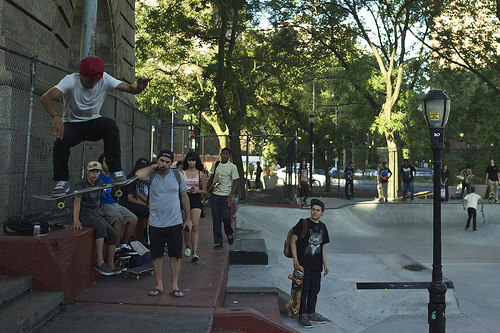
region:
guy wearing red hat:
[73, 53, 109, 85]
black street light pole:
[411, 81, 461, 331]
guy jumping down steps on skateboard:
[16, 50, 161, 217]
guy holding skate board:
[276, 190, 337, 328]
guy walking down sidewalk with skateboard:
[204, 139, 245, 256]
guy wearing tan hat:
[82, 155, 109, 176]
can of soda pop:
[30, 219, 42, 239]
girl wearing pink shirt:
[174, 153, 211, 199]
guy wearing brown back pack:
[279, 191, 332, 331]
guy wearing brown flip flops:
[143, 281, 187, 302]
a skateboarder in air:
[31, 56, 154, 206]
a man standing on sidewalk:
[132, 150, 192, 301]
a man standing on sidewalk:
[283, 198, 331, 330]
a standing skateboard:
[285, 260, 304, 318]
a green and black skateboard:
[31, 170, 142, 210]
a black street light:
[416, 81, 453, 331]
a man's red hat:
[75, 54, 103, 74]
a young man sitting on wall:
[75, 159, 120, 280]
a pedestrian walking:
[205, 145, 239, 250]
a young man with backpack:
[281, 199, 331, 327]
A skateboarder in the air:
[27, 55, 154, 210]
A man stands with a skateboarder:
[285, 192, 327, 332]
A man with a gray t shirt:
[140, 150, 193, 305]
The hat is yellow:
[84, 158, 104, 172]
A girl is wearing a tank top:
[183, 149, 205, 204]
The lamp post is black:
[419, 90, 466, 331]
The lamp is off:
[417, 85, 452, 151]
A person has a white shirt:
[463, 183, 488, 231]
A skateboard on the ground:
[128, 265, 156, 280]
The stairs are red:
[226, 285, 315, 331]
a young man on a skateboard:
[35, 50, 151, 222]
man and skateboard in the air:
[26, 55, 153, 244]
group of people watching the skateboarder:
[32, 47, 262, 293]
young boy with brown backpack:
[282, 191, 339, 329]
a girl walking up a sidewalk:
[176, 147, 233, 281]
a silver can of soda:
[29, 217, 44, 243]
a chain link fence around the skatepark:
[2, 31, 497, 259]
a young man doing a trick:
[26, 52, 164, 210]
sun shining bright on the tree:
[357, 30, 412, 200]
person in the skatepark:
[276, 201, 340, 321]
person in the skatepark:
[146, 145, 193, 303]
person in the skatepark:
[45, 65, 120, 189]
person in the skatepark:
[446, 185, 487, 241]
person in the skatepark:
[205, 140, 238, 243]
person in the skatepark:
[80, 161, 118, 254]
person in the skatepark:
[170, 146, 206, 221]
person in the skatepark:
[362, 157, 402, 207]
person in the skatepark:
[293, 153, 313, 199]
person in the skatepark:
[334, 160, 359, 190]